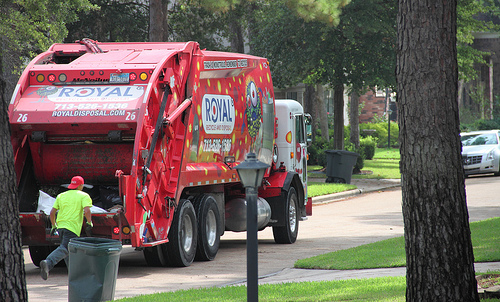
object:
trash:
[67, 237, 123, 302]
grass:
[115, 274, 497, 299]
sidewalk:
[59, 179, 499, 300]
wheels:
[192, 194, 222, 261]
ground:
[0, 148, 500, 302]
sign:
[202, 94, 236, 135]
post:
[244, 187, 259, 302]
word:
[205, 98, 232, 123]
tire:
[271, 186, 300, 243]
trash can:
[325, 149, 359, 183]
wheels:
[336, 178, 344, 183]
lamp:
[234, 153, 269, 187]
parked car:
[460, 129, 500, 178]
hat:
[67, 176, 84, 189]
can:
[66, 237, 121, 302]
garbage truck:
[6, 37, 313, 266]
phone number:
[55, 104, 129, 110]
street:
[2, 131, 499, 301]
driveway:
[249, 259, 493, 288]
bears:
[40, 175, 94, 280]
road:
[10, 161, 499, 302]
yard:
[112, 265, 491, 302]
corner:
[313, 182, 401, 209]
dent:
[70, 263, 102, 299]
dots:
[197, 61, 201, 71]